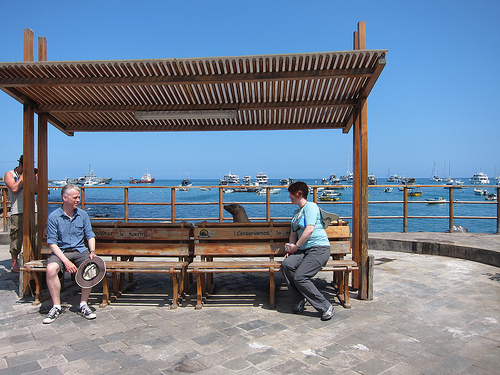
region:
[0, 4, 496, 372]
Strangers see a seal in the harbor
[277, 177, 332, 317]
A woman is looking at something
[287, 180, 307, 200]
woman has dark short hair and fair skin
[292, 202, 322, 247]
The woman's shirt is blue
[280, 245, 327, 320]
The woman has on grey cargo pants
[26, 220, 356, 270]
there is a bench for people to sit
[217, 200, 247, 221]
the head of a seal animal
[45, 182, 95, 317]
man wearing blue shirt and brown shorts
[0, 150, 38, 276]
There is a man photographing the animal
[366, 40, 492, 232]
The sky and water are almost the same color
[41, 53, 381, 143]
covering on large wooden bench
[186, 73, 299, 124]
slats on the covering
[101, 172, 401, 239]
large brass railing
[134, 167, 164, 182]
white boat in harbor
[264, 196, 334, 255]
blue shirt with short sleeve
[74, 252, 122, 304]
hat in man's hand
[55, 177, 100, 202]
man's salt and pepper hair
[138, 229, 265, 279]
rust on brown bench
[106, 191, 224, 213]
blue water in the bay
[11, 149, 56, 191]
man taking picture on the side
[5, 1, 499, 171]
The sky is clear blue.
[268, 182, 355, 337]
She is sitting.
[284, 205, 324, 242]
She has a blue shirt on.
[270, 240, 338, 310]
She has grey pants on.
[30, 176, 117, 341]
He is sitting.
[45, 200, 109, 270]
He has a blue shirt on.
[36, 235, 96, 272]
He has grey shorts on.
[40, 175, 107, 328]
He is holding a hat.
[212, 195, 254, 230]
The seal is sitting on the bench.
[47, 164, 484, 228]
The water is calm.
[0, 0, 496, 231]
The sky is clear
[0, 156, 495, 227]
There are many boats at sea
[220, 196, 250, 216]
A sea lion is sitting on the bench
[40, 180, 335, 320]
Two people sitting on the benches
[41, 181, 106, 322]
One man is holding a hat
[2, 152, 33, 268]
One man is standing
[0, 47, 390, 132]
There is a awing above the benches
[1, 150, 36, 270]
The man stand is wearing a hat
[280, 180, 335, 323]
The lady has red hair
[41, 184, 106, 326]
The man holding the hat has a blue shirt on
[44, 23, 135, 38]
blue sky with no clouds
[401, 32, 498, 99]
blue sky with no clouds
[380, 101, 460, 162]
blue sky with no clouds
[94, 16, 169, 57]
blue sky with no clouds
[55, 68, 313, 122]
browwn wooden structure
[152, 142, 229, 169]
blue sky with no clouds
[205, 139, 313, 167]
blue sky with no clouds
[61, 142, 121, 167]
blue sky with no clouds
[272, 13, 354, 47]
blue sky with no clouds